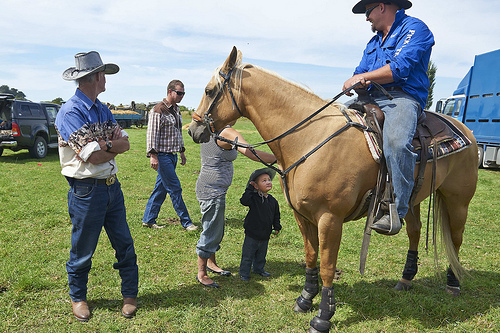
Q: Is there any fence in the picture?
A: No, there are no fences.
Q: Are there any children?
A: Yes, there is a child.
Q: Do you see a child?
A: Yes, there is a child.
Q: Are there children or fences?
A: Yes, there is a child.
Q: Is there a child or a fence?
A: Yes, there is a child.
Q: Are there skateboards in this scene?
A: No, there are no skateboards.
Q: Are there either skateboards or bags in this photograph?
A: No, there are no skateboards or bags.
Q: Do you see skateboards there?
A: No, there are no skateboards.